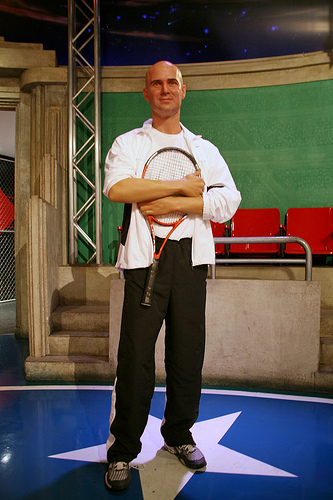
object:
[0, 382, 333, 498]
floor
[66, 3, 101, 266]
tower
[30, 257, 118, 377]
steps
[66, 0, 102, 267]
railing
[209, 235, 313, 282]
metal railing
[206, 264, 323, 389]
wall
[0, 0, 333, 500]
structure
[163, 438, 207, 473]
foot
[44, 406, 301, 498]
star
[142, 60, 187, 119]
head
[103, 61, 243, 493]
andre agassi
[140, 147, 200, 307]
racket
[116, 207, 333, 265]
chairs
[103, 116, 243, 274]
white jacket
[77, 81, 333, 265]
wall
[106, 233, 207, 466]
black pants